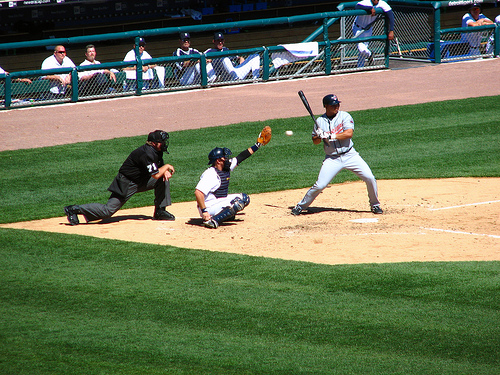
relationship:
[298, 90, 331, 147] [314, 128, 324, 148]
bat in hand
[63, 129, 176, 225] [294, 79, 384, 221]
an umpire behind batter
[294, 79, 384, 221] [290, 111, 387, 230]
batter in light grey uniform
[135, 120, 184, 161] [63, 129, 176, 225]
black mask on an umpire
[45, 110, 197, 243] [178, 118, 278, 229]
an umpire behind catcher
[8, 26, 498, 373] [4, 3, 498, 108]
baseball field has dugout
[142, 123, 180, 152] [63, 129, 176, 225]
head on an umpire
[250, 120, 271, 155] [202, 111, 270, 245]
hand on man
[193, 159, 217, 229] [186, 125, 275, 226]
arm on man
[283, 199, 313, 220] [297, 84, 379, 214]
foot on man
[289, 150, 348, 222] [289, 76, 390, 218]
leg on man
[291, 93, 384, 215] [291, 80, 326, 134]
batter holding bat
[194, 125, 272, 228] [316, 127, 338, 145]
catcher wearing baseball glove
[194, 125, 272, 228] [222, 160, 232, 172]
catcher wearing black catcher's mask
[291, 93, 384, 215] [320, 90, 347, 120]
batter wearing wearing a hat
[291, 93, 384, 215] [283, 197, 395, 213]
batter wearing shoes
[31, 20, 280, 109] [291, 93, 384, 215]
people watching watching batter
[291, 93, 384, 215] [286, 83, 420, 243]
batter dressed in grey outfit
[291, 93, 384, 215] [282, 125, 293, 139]
batter hitting ball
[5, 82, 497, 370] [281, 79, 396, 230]
floor has white stripes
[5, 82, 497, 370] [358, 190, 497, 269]
floor has white stripes